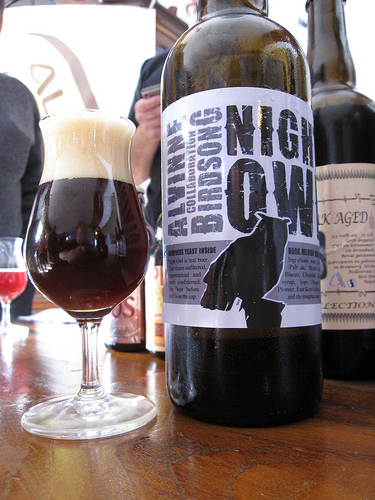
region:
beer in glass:
[15, 100, 161, 417]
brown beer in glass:
[31, 114, 155, 444]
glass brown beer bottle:
[169, 9, 310, 412]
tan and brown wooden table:
[138, 450, 184, 477]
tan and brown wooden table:
[216, 446, 253, 484]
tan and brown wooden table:
[281, 453, 316, 477]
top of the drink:
[38, 98, 135, 166]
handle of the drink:
[54, 311, 129, 386]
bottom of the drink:
[40, 368, 155, 445]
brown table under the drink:
[155, 426, 241, 489]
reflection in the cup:
[24, 182, 129, 272]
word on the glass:
[162, 101, 323, 255]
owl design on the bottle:
[181, 196, 313, 306]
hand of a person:
[127, 90, 168, 144]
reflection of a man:
[51, 221, 104, 266]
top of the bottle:
[298, 9, 358, 71]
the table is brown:
[162, 428, 365, 498]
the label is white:
[166, 99, 320, 331]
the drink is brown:
[40, 179, 150, 315]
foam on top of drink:
[47, 118, 134, 186]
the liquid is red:
[3, 266, 22, 303]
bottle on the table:
[185, 17, 335, 430]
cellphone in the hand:
[142, 83, 180, 169]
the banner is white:
[6, 8, 144, 121]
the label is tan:
[323, 168, 372, 326]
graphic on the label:
[205, 205, 294, 329]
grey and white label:
[158, 25, 294, 381]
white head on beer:
[24, 119, 140, 188]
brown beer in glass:
[30, 178, 142, 329]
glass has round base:
[31, 314, 179, 457]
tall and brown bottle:
[142, 38, 333, 434]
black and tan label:
[301, 166, 373, 346]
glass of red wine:
[1, 234, 29, 322]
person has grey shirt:
[0, 86, 39, 228]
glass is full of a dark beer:
[21, 96, 161, 450]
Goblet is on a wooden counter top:
[7, 314, 361, 498]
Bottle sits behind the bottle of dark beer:
[278, 1, 373, 423]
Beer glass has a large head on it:
[35, 103, 142, 200]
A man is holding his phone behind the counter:
[118, 38, 217, 213]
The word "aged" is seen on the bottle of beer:
[335, 209, 371, 230]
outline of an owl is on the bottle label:
[184, 204, 324, 345]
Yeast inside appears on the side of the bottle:
[182, 242, 224, 258]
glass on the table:
[10, 115, 153, 292]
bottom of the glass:
[34, 375, 157, 459]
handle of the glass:
[66, 317, 127, 370]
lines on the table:
[90, 411, 218, 498]